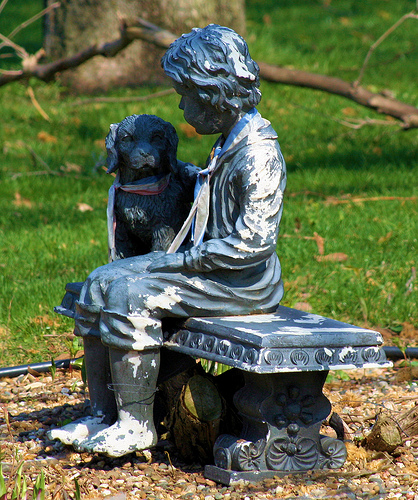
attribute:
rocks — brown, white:
[0, 369, 416, 498]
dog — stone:
[103, 111, 179, 254]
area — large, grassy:
[249, 7, 415, 99]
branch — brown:
[1, 0, 417, 123]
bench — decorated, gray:
[59, 285, 392, 487]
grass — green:
[1, 1, 416, 369]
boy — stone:
[46, 31, 286, 459]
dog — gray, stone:
[98, 114, 201, 257]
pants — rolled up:
[71, 247, 283, 341]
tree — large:
[48, 2, 248, 94]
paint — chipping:
[81, 421, 164, 457]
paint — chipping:
[49, 408, 108, 448]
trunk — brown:
[159, 362, 230, 471]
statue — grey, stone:
[45, 23, 395, 489]